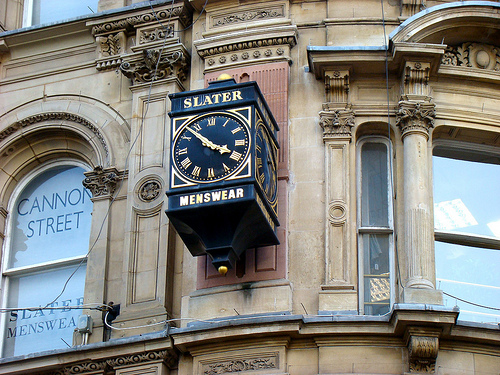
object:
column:
[385, 39, 462, 328]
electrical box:
[73, 314, 93, 349]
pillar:
[1, 0, 498, 373]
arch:
[385, 1, 499, 72]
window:
[431, 140, 497, 322]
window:
[347, 111, 404, 316]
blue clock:
[168, 87, 252, 178]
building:
[74, 53, 452, 315]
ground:
[442, 120, 465, 157]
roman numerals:
[213, 115, 243, 134]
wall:
[166, 0, 321, 346]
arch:
[5, 97, 121, 338]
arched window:
[2, 158, 93, 363]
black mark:
[221, 277, 267, 303]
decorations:
[202, 8, 289, 65]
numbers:
[175, 116, 243, 176]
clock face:
[172, 111, 251, 184]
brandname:
[164, 83, 264, 109]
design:
[375, 44, 447, 367]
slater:
[174, 82, 262, 112]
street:
[0, 85, 170, 373]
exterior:
[4, 15, 498, 357]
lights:
[440, 161, 486, 279]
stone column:
[310, 26, 372, 320]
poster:
[9, 171, 96, 361]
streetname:
[8, 179, 93, 262]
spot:
[229, 273, 262, 311]